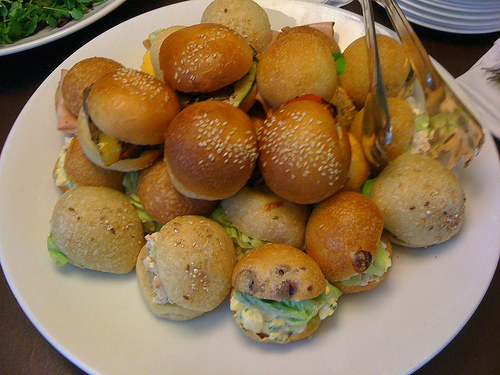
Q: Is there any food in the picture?
A: Yes, there is food.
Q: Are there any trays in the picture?
A: No, there are no trays.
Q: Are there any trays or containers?
A: No, there are no trays or containers.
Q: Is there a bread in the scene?
A: Yes, there is a bread.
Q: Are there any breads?
A: Yes, there is a bread.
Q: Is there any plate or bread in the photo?
A: Yes, there is a bread.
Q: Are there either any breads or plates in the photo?
A: Yes, there is a bread.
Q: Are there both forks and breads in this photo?
A: No, there is a bread but no forks.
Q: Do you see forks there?
A: No, there are no forks.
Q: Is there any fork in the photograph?
A: No, there are no forks.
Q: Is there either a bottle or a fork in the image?
A: No, there are no forks or bottles.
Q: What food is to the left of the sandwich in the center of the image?
A: The food is a bread.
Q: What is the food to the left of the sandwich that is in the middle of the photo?
A: The food is a bread.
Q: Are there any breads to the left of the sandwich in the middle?
A: Yes, there is a bread to the left of the sandwich.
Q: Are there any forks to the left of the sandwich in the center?
A: No, there is a bread to the left of the sandwich.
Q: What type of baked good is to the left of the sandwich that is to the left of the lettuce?
A: The food is a bread.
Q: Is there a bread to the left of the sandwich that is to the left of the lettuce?
A: Yes, there is a bread to the left of the sandwich.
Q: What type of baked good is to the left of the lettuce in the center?
A: The food is a bread.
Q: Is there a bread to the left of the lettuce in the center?
A: Yes, there is a bread to the left of the lettuce.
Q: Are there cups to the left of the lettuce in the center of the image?
A: No, there is a bread to the left of the lettuce.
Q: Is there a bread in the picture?
A: Yes, there is a bread.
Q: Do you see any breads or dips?
A: Yes, there is a bread.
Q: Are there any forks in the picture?
A: No, there are no forks.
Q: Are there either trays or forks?
A: No, there are no forks or trays.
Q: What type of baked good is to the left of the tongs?
A: The food is a bread.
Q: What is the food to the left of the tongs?
A: The food is a bread.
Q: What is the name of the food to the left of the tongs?
A: The food is a bread.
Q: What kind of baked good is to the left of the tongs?
A: The food is a bread.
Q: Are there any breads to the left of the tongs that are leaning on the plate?
A: Yes, there is a bread to the left of the tongs.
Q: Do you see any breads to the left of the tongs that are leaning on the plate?
A: Yes, there is a bread to the left of the tongs.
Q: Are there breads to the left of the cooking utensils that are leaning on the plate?
A: Yes, there is a bread to the left of the tongs.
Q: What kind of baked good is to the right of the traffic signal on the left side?
A: The food is a bread.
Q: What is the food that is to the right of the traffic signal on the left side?
A: The food is a bread.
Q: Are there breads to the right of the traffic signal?
A: Yes, there is a bread to the right of the traffic signal.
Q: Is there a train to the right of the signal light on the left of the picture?
A: No, there is a bread to the right of the traffic light.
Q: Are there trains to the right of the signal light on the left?
A: No, there is a bread to the right of the traffic light.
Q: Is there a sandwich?
A: Yes, there is a sandwich.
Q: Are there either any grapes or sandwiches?
A: Yes, there is a sandwich.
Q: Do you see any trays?
A: No, there are no trays.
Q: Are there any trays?
A: No, there are no trays.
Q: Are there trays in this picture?
A: No, there are no trays.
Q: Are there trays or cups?
A: No, there are no trays or cups.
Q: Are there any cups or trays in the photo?
A: No, there are no trays or cups.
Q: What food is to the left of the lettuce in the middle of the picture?
A: The food is a sandwich.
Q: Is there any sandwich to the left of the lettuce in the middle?
A: Yes, there is a sandwich to the left of the lettuce.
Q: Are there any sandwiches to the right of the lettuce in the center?
A: No, the sandwich is to the left of the lettuce.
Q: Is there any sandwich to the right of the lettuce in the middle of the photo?
A: No, the sandwich is to the left of the lettuce.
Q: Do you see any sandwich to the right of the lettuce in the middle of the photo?
A: No, the sandwich is to the left of the lettuce.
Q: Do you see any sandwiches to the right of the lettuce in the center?
A: No, the sandwich is to the left of the lettuce.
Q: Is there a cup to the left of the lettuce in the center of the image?
A: No, there is a sandwich to the left of the lettuce.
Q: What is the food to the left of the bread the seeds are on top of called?
A: The food is a sandwich.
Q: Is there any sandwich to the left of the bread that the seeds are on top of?
A: Yes, there is a sandwich to the left of the bread.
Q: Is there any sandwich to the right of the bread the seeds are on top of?
A: No, the sandwich is to the left of the bread.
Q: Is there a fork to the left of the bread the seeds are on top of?
A: No, there is a sandwich to the left of the bread.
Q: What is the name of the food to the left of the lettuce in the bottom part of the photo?
A: The food is a sandwich.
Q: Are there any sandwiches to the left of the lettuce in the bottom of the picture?
A: Yes, there is a sandwich to the left of the lettuce.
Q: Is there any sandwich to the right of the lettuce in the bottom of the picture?
A: No, the sandwich is to the left of the lettuce.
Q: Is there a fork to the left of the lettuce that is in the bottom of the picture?
A: No, there is a sandwich to the left of the lettuce.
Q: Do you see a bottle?
A: No, there are no bottles.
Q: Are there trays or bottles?
A: No, there are no bottles or trays.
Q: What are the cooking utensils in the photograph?
A: The cooking utensils are tongs.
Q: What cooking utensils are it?
A: The cooking utensils are tongs.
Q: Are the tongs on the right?
A: Yes, the tongs are on the right of the image.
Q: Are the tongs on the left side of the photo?
A: No, the tongs are on the right of the image.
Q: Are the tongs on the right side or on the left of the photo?
A: The tongs are on the right of the image.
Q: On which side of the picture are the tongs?
A: The tongs are on the right of the image.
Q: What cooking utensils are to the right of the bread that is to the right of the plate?
A: The cooking utensils are tongs.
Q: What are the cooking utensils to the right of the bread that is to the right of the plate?
A: The cooking utensils are tongs.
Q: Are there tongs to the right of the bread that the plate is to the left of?
A: Yes, there are tongs to the right of the bread.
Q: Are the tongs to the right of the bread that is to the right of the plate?
A: Yes, the tongs are to the right of the bread.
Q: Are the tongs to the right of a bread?
A: Yes, the tongs are to the right of a bread.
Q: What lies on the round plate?
A: The tongs lie on the plate.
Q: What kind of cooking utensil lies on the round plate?
A: The cooking utensils are tongs.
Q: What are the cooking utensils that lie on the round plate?
A: The cooking utensils are tongs.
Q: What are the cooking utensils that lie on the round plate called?
A: The cooking utensils are tongs.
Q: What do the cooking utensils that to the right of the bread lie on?
A: The tongs lie on the plate.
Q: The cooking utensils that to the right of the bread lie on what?
A: The tongs lie on the plate.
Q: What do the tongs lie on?
A: The tongs lie on the plate.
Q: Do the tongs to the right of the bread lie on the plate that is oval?
A: Yes, the tongs lie on the plate.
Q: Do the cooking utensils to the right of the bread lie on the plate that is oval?
A: Yes, the tongs lie on the plate.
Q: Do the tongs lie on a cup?
A: No, the tongs lie on the plate.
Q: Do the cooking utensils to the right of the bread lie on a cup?
A: No, the tongs lie on the plate.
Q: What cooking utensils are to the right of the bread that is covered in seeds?
A: The cooking utensils are tongs.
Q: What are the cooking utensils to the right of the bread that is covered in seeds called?
A: The cooking utensils are tongs.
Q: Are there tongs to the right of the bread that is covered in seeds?
A: Yes, there are tongs to the right of the bread.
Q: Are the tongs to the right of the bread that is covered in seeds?
A: Yes, the tongs are to the right of the bread.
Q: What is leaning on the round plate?
A: The tongs are leaning on the plate.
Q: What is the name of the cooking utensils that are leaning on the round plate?
A: The cooking utensils are tongs.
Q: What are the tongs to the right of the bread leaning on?
A: The tongs are leaning on the plate.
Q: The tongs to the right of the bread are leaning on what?
A: The tongs are leaning on the plate.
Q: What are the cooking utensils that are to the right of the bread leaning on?
A: The tongs are leaning on the plate.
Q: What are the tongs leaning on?
A: The tongs are leaning on the plate.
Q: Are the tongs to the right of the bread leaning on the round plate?
A: Yes, the tongs are leaning on the plate.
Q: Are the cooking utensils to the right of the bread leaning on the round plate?
A: Yes, the tongs are leaning on the plate.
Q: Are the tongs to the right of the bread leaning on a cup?
A: No, the tongs are leaning on the plate.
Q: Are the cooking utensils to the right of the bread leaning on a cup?
A: No, the tongs are leaning on the plate.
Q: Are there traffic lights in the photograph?
A: Yes, there is a traffic light.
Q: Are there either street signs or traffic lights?
A: Yes, there is a traffic light.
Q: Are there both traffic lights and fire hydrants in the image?
A: No, there is a traffic light but no fire hydrants.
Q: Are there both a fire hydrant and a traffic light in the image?
A: No, there is a traffic light but no fire hydrants.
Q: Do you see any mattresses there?
A: No, there are no mattresses.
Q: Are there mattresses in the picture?
A: No, there are no mattresses.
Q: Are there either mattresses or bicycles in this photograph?
A: No, there are no mattresses or bicycles.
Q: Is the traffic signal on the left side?
A: Yes, the traffic signal is on the left of the image.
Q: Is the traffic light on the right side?
A: No, the traffic light is on the left of the image.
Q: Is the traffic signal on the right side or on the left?
A: The traffic signal is on the left of the image.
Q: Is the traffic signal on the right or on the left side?
A: The traffic signal is on the left of the image.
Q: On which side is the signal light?
A: The signal light is on the left of the image.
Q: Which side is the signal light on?
A: The signal light is on the left of the image.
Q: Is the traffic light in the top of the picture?
A: Yes, the traffic light is in the top of the image.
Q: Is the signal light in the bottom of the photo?
A: No, the signal light is in the top of the image.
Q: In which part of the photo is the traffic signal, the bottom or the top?
A: The traffic signal is in the top of the image.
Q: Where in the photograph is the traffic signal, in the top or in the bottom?
A: The traffic signal is in the top of the image.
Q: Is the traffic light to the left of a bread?
A: Yes, the traffic light is to the left of a bread.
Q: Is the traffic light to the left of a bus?
A: No, the traffic light is to the left of a bread.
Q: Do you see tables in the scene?
A: Yes, there is a table.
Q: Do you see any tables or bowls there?
A: Yes, there is a table.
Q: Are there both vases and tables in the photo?
A: No, there is a table but no vases.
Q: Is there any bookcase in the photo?
A: No, there are no bookcases.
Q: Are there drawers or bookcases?
A: No, there are no bookcases or drawers.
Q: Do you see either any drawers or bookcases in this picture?
A: No, there are no bookcases or drawers.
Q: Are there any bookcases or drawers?
A: No, there are no bookcases or drawers.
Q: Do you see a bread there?
A: Yes, there is a bread.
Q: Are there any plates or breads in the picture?
A: Yes, there is a bread.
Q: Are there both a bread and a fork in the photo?
A: No, there is a bread but no forks.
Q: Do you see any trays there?
A: No, there are no trays.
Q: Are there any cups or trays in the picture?
A: No, there are no trays or cups.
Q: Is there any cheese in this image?
A: Yes, there is cheese.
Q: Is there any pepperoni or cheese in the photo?
A: Yes, there is cheese.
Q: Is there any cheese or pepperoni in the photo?
A: Yes, there is cheese.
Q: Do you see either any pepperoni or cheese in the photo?
A: Yes, there is cheese.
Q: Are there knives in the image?
A: No, there are no knives.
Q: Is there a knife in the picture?
A: No, there are no knives.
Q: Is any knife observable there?
A: No, there are no knives.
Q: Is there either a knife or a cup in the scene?
A: No, there are no knives or cups.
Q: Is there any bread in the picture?
A: Yes, there is a bread.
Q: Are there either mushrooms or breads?
A: Yes, there is a bread.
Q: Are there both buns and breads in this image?
A: Yes, there are both a bread and a bun.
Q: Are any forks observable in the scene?
A: No, there are no forks.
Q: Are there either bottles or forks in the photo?
A: No, there are no forks or bottles.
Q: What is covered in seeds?
A: The bread is covered in seeds.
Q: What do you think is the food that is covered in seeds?
A: The food is a bread.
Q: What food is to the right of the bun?
A: The food is a bread.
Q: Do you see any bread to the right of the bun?
A: Yes, there is a bread to the right of the bun.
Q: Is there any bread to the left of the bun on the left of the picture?
A: No, the bread is to the right of the bun.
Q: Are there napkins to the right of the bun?
A: No, there is a bread to the right of the bun.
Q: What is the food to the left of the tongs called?
A: The food is a bread.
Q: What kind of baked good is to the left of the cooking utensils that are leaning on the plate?
A: The food is a bread.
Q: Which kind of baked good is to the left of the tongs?
A: The food is a bread.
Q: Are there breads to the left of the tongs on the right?
A: Yes, there is a bread to the left of the tongs.